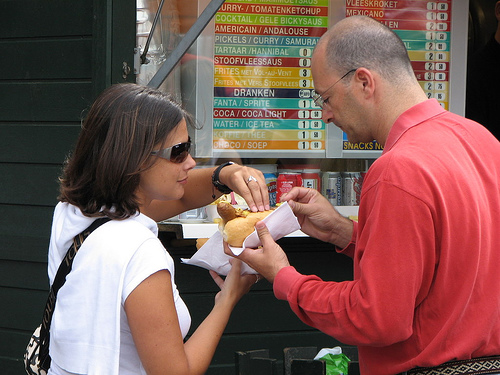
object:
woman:
[42, 82, 271, 375]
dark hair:
[56, 80, 207, 218]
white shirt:
[49, 200, 196, 375]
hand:
[224, 222, 292, 279]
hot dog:
[222, 203, 308, 249]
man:
[220, 13, 500, 375]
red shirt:
[267, 98, 500, 375]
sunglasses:
[145, 137, 201, 165]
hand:
[214, 163, 273, 213]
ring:
[244, 174, 257, 183]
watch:
[211, 156, 238, 194]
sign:
[197, 0, 456, 155]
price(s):
[296, 44, 320, 149]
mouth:
[177, 172, 189, 185]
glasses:
[304, 72, 367, 108]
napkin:
[227, 201, 302, 256]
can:
[321, 171, 344, 208]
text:
[215, 33, 319, 47]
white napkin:
[178, 233, 259, 277]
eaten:
[192, 181, 301, 258]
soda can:
[344, 169, 363, 209]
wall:
[2, 0, 139, 375]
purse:
[23, 214, 112, 375]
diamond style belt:
[389, 353, 492, 375]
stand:
[0, 0, 500, 375]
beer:
[274, 171, 304, 201]